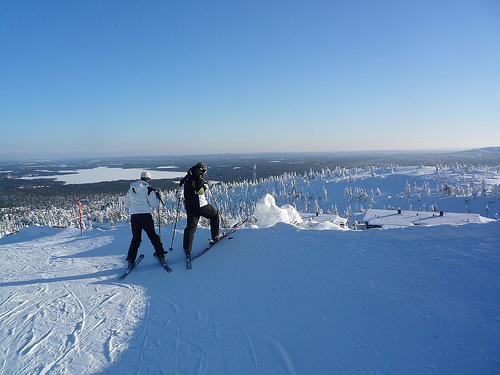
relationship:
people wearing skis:
[126, 172, 168, 258] [123, 253, 170, 279]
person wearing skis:
[178, 163, 222, 255] [180, 225, 235, 269]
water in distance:
[55, 168, 142, 181] [8, 141, 214, 158]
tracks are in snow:
[16, 291, 94, 363] [104, 291, 499, 374]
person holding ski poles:
[178, 163, 222, 255] [166, 198, 181, 252]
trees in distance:
[60, 192, 104, 213] [8, 141, 214, 158]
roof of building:
[362, 206, 482, 224] [362, 223, 486, 236]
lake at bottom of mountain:
[11, 165, 196, 186] [18, 151, 493, 372]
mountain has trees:
[18, 151, 493, 372] [60, 192, 104, 213]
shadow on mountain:
[94, 285, 241, 372] [18, 151, 493, 372]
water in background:
[55, 168, 142, 181] [17, 153, 492, 168]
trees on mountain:
[60, 192, 104, 213] [18, 151, 493, 372]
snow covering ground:
[104, 291, 499, 374] [10, 222, 498, 365]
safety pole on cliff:
[76, 205, 84, 238] [41, 215, 498, 244]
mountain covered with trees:
[18, 151, 493, 372] [60, 192, 104, 213]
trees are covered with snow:
[60, 192, 104, 213] [104, 291, 499, 374]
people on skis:
[126, 160, 223, 258] [123, 253, 170, 279]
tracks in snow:
[16, 291, 94, 363] [104, 291, 499, 374]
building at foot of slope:
[362, 223, 486, 236] [350, 203, 499, 369]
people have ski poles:
[126, 172, 168, 258] [166, 198, 181, 252]